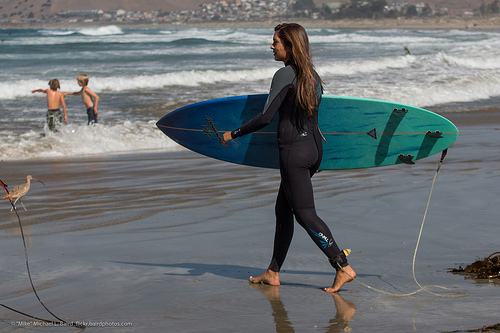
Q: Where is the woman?
A: On the beach.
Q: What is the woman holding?
A: Surfboard.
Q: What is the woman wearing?
A: Wetsuit.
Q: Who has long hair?
A: The woman.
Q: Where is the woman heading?
A: The water.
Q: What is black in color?
A: Wetsuit.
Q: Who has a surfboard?
A: The woman.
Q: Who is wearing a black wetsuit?
A: The woman with the surfboard.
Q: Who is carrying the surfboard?
A: The woman wearing a wetsuit.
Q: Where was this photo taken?
A: Near the ocean.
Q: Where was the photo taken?
A: At a beach.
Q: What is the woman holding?
A: A surfboard.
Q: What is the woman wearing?
A: A wetsuit.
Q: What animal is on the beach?
A: A bird.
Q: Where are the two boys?
A: In the water.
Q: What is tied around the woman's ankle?
A: A safety tether.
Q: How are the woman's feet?
A: Bare.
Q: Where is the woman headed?
A: Toward the water.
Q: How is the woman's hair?
A: Dry.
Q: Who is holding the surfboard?
A: The woman.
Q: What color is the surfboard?
A: Green and blue.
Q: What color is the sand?
A: Brown.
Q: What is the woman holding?
A: A surfboard.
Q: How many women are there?
A: One.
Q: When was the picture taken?
A: Daytime.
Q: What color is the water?
A: Blue and white.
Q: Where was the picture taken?
A: Ocean.